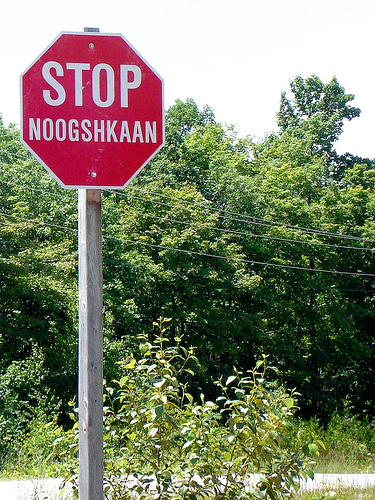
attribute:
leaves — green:
[3, 73, 374, 496]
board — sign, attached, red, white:
[19, 25, 168, 190]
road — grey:
[4, 455, 373, 495]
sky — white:
[0, 1, 373, 163]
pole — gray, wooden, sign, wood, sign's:
[76, 189, 110, 498]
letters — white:
[26, 60, 162, 147]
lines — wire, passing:
[0, 173, 374, 279]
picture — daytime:
[6, 0, 373, 492]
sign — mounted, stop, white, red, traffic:
[13, 24, 181, 191]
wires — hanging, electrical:
[0, 170, 373, 282]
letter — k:
[103, 117, 126, 145]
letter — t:
[65, 57, 92, 114]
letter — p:
[117, 61, 144, 109]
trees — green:
[3, 71, 373, 421]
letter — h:
[92, 117, 106, 144]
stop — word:
[39, 58, 147, 112]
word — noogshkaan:
[22, 115, 163, 145]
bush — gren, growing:
[60, 303, 326, 496]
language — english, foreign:
[24, 61, 158, 140]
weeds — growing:
[28, 312, 331, 499]